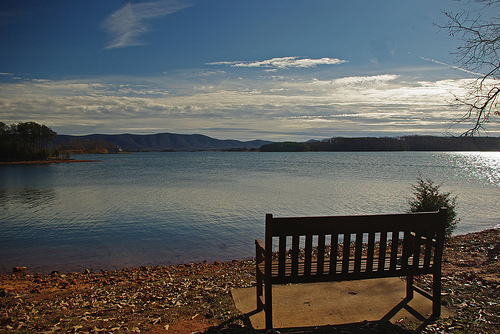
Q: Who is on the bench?
A: The bench is empty.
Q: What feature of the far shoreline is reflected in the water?
A: The trees.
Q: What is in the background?
A: The hilltops.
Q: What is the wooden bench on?
A: The legs.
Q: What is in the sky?
A: The long line of clouds.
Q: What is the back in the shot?
A: The wooden bench.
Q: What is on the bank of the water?
A: The bench.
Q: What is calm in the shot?
A: The water.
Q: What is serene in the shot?
A: The water.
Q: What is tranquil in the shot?
A: The water.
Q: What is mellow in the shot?
A: The water.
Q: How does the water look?
A: Calm.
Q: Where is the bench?
A: Next to the water.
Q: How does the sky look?
A: Blue with white clouds.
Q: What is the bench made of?
A: Wood.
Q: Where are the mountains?
A: On the horizon.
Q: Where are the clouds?
A: In the sky.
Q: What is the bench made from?
A: Wood.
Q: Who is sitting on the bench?
A: There is nobody on the bench.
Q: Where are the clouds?
A: In the sky.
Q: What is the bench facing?
A: The water.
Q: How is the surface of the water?
A: Calm with a few ripples.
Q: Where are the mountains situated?
A: Beyond the water.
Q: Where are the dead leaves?
A: Next to the bench.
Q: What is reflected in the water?
A: Trees and sky.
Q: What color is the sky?
A: Blue.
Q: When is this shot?
A: Daytime.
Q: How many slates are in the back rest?
A: 15.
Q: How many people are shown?
A: 0.